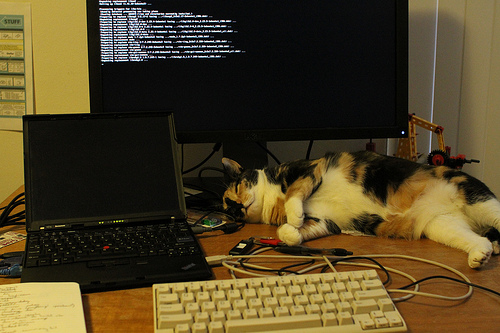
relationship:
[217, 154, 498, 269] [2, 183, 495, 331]
cat sleeping on desk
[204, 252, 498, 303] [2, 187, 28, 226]
cables and cords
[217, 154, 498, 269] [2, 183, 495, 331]
cat laying on desk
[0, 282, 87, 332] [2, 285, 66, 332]
note book with writing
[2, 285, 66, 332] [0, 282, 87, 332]
writing on a note book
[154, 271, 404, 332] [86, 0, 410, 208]
computer keyboard for computer monitor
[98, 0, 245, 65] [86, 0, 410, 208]
scripts on computer monitor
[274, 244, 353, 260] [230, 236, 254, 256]
pen and a thumb drive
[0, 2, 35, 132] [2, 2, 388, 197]
paper on wall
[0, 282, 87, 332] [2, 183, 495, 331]
note book on desk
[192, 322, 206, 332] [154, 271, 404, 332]
key on computer keyboard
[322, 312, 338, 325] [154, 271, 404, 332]
key on computer keyboard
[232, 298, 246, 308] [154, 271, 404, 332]
key on computer keyboard